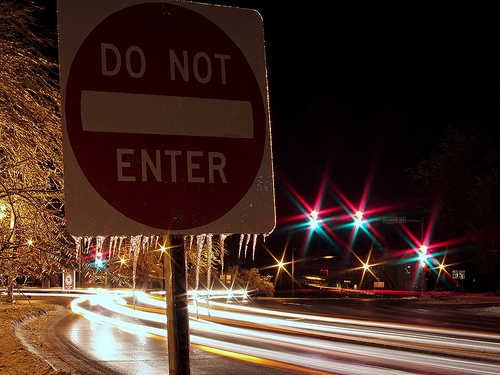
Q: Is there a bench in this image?
A: No, there are no benches.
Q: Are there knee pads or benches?
A: No, there are no benches or knee pads.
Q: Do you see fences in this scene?
A: No, there are no fences.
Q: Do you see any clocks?
A: No, there are no clocks.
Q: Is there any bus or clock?
A: No, there are no clocks or buses.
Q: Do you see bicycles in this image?
A: No, there are no bicycles.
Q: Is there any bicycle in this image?
A: No, there are no bicycles.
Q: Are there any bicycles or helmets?
A: No, there are no bicycles or helmets.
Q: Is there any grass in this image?
A: Yes, there is grass.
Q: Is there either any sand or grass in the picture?
A: Yes, there is grass.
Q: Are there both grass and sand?
A: No, there is grass but no sand.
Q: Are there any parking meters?
A: No, there are no parking meters.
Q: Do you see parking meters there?
A: No, there are no parking meters.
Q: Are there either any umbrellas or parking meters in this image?
A: No, there are no parking meters or umbrellas.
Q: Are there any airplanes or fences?
A: No, there are no fences or airplanes.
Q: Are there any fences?
A: No, there are no fences.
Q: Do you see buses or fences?
A: No, there are no fences or buses.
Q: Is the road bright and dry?
A: No, the road is bright but wet.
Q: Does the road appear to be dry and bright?
A: No, the road is bright but wet.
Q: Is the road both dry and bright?
A: No, the road is bright but wet.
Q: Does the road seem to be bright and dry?
A: No, the road is bright but wet.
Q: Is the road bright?
A: Yes, the road is bright.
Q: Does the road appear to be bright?
A: Yes, the road is bright.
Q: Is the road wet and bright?
A: Yes, the road is wet and bright.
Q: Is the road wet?
A: Yes, the road is wet.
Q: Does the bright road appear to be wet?
A: Yes, the road is wet.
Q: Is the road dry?
A: No, the road is wet.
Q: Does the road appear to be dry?
A: No, the road is wet.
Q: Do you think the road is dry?
A: No, the road is wet.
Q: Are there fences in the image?
A: No, there are no fences.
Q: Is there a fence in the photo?
A: No, there are no fences.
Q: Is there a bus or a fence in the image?
A: No, there are no fences or buses.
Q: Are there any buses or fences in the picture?
A: No, there are no fences or buses.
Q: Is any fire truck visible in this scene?
A: No, there are no fire trucks.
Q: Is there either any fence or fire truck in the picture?
A: No, there are no fire trucks or fences.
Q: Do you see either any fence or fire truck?
A: No, there are no fire trucks or fences.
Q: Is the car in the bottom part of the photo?
A: Yes, the car is in the bottom of the image.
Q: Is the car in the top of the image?
A: No, the car is in the bottom of the image.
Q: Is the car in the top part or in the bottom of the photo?
A: The car is in the bottom of the image.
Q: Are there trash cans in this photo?
A: No, there are no trash cans.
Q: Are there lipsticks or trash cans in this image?
A: No, there are no trash cans or lipsticks.